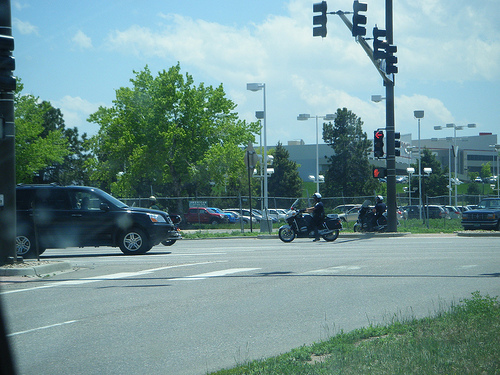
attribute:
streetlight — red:
[372, 130, 384, 159]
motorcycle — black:
[352, 195, 400, 235]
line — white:
[1, 256, 231, 298]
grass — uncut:
[191, 291, 499, 374]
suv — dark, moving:
[13, 183, 186, 258]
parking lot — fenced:
[160, 200, 495, 228]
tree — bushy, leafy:
[80, 61, 262, 230]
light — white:
[246, 79, 267, 95]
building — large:
[123, 134, 500, 208]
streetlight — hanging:
[311, 1, 330, 39]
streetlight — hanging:
[351, 1, 369, 39]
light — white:
[370, 92, 384, 104]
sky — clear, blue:
[10, 2, 499, 175]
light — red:
[373, 130, 385, 142]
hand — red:
[372, 165, 380, 181]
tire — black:
[116, 222, 152, 257]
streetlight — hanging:
[371, 23, 390, 65]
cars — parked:
[175, 203, 294, 227]